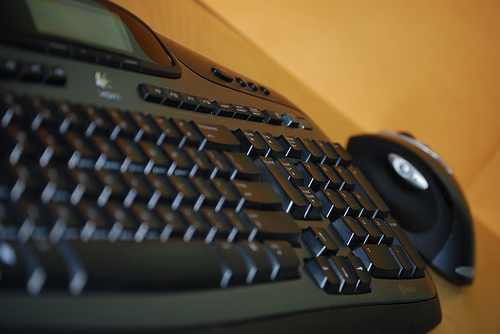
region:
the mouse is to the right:
[360, 95, 488, 287]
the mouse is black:
[357, 99, 478, 294]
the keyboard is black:
[10, 105, 438, 317]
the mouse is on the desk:
[316, 99, 480, 303]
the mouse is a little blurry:
[360, 92, 496, 304]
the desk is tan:
[445, 280, 492, 327]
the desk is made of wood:
[432, 282, 494, 329]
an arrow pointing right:
[344, 255, 369, 279]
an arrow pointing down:
[333, 256, 356, 284]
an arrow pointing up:
[310, 217, 338, 249]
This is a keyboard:
[12, 5, 434, 332]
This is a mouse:
[342, 100, 487, 304]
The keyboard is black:
[1, 3, 446, 327]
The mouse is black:
[334, 98, 483, 300]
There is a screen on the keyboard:
[26, 0, 143, 67]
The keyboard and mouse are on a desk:
[6, 2, 498, 329]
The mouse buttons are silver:
[380, 147, 437, 202]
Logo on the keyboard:
[90, 63, 132, 113]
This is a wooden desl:
[141, 7, 393, 161]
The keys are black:
[2, 82, 425, 314]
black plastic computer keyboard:
[0, 0, 442, 332]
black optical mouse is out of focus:
[347, 131, 474, 286]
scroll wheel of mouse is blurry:
[397, 130, 414, 140]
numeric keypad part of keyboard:
[275, 134, 425, 279]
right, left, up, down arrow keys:
[302, 225, 371, 292]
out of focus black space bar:
[57, 239, 220, 295]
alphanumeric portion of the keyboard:
[0, 90, 300, 293]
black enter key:
[229, 178, 282, 210]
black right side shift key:
[240, 208, 300, 247]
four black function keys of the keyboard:
[138, 82, 213, 112]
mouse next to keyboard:
[344, 113, 483, 299]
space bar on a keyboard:
[61, 244, 226, 297]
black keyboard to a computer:
[11, 42, 447, 325]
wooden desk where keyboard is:
[191, 9, 241, 61]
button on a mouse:
[392, 120, 424, 150]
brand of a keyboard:
[83, 64, 133, 101]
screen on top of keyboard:
[24, 1, 154, 63]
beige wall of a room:
[318, 19, 483, 114]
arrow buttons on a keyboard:
[302, 218, 367, 299]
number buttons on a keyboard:
[296, 156, 399, 250]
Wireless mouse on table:
[342, 127, 477, 287]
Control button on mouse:
[387, 149, 428, 196]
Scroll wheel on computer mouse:
[396, 127, 416, 142]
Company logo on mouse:
[452, 264, 476, 280]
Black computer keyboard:
[0, 46, 444, 331]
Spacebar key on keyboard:
[52, 239, 224, 296]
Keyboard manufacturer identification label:
[90, 69, 122, 101]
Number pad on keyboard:
[298, 157, 423, 277]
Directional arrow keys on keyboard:
[303, 224, 371, 296]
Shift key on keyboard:
[241, 209, 303, 241]